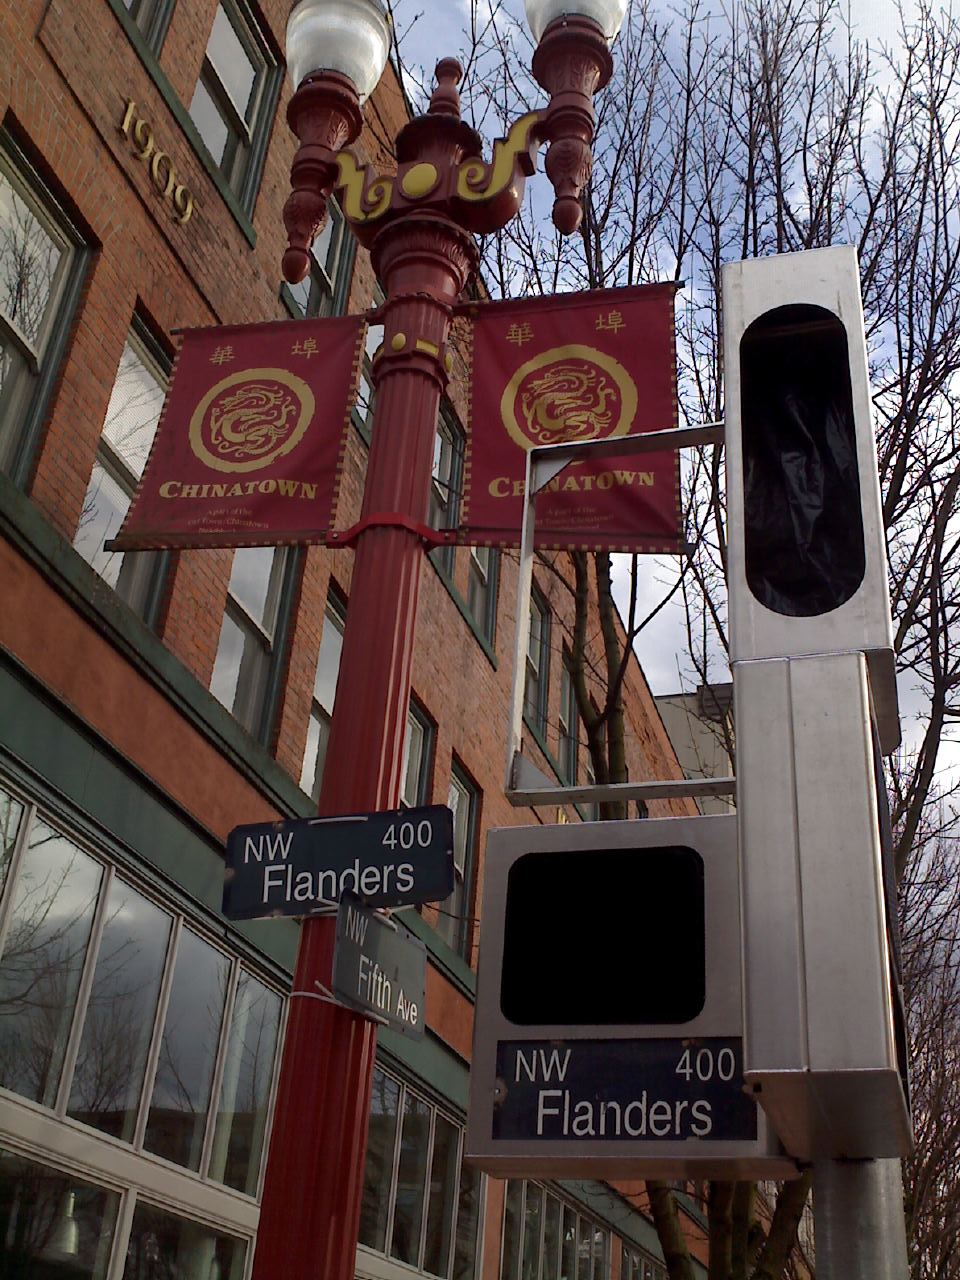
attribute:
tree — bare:
[384, 3, 932, 1275]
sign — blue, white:
[486, 1040, 760, 1142]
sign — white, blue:
[328, 883, 430, 1041]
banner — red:
[104, 295, 348, 544]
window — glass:
[72, 437, 145, 597]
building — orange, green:
[2, 7, 749, 1277]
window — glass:
[197, 594, 287, 733]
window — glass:
[208, 534, 302, 635]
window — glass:
[274, 695, 336, 796]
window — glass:
[382, 698, 437, 809]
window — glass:
[456, 566, 511, 646]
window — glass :
[100, 904, 318, 1211]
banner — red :
[485, 288, 663, 528]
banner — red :
[54, 288, 375, 612]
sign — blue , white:
[250, 787, 513, 1031]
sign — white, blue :
[423, 980, 810, 1201]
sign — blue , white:
[273, 788, 482, 1049]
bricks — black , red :
[386, 588, 502, 759]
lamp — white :
[744, 705, 862, 1059]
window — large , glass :
[30, 837, 232, 1247]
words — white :
[491, 994, 808, 1233]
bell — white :
[51, 1171, 112, 1268]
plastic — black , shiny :
[733, 254, 893, 742]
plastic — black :
[414, 799, 756, 1031]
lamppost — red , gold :
[128, 22, 613, 980]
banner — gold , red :
[412, 293, 682, 514]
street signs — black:
[212, 799, 470, 943]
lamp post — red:
[243, 202, 496, 1275]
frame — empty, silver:
[502, 415, 737, 809]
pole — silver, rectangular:
[456, 230, 930, 1275]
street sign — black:
[496, 1040, 752, 1153]